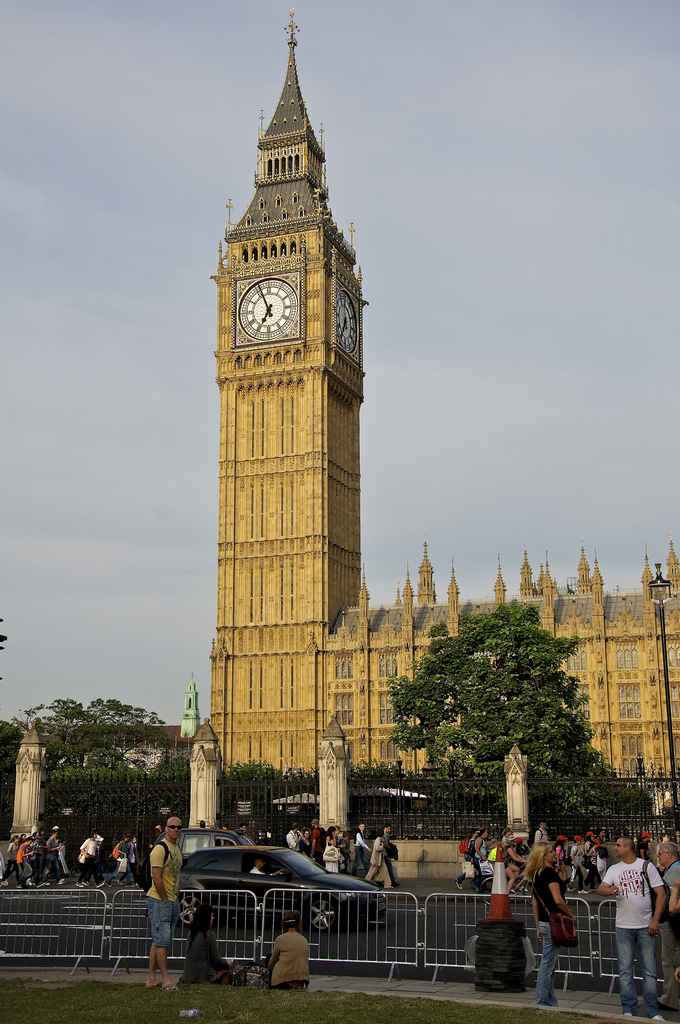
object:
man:
[140, 813, 185, 992]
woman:
[521, 833, 582, 1009]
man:
[597, 835, 666, 1012]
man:
[266, 908, 311, 991]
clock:
[232, 268, 310, 350]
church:
[180, 671, 201, 736]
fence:
[5, 881, 676, 994]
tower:
[203, 8, 372, 783]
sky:
[7, 6, 678, 543]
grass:
[1, 983, 654, 1022]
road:
[13, 883, 668, 967]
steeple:
[212, 0, 341, 218]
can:
[470, 924, 528, 991]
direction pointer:
[280, 9, 303, 44]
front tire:
[307, 897, 336, 930]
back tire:
[180, 895, 203, 925]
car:
[168, 841, 384, 934]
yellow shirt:
[148, 849, 204, 909]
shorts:
[145, 891, 181, 948]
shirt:
[532, 866, 566, 921]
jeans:
[610, 923, 658, 1017]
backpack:
[136, 841, 169, 886]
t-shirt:
[605, 855, 661, 930]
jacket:
[272, 929, 309, 982]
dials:
[256, 282, 273, 318]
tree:
[401, 600, 634, 849]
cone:
[477, 837, 522, 925]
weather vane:
[280, 5, 303, 41]